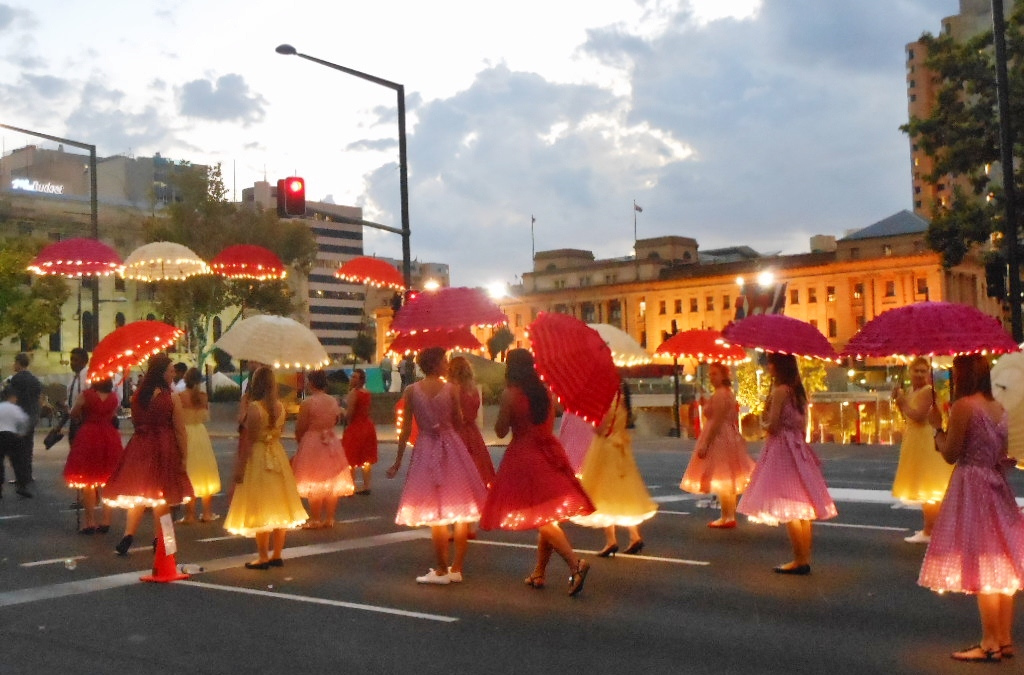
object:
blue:
[0, 0, 983, 290]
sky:
[0, 0, 960, 292]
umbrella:
[528, 313, 620, 428]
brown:
[780, 357, 796, 376]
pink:
[735, 395, 838, 526]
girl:
[222, 368, 309, 569]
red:
[285, 177, 305, 198]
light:
[277, 177, 305, 218]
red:
[480, 388, 596, 531]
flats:
[567, 559, 591, 597]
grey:
[116, 635, 167, 653]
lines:
[20, 555, 87, 566]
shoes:
[708, 516, 738, 529]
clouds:
[61, 71, 270, 153]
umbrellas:
[28, 237, 286, 282]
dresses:
[222, 388, 377, 537]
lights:
[396, 501, 583, 530]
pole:
[398, 82, 410, 287]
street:
[0, 390, 1024, 675]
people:
[62, 347, 657, 597]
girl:
[915, 355, 1018, 663]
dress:
[917, 396, 1021, 594]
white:
[465, 539, 710, 565]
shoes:
[416, 567, 462, 585]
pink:
[847, 302, 1019, 357]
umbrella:
[841, 301, 1020, 358]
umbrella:
[28, 238, 120, 277]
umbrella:
[123, 242, 209, 282]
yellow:
[223, 400, 309, 538]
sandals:
[562, 559, 590, 596]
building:
[643, 258, 749, 354]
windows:
[659, 296, 714, 315]